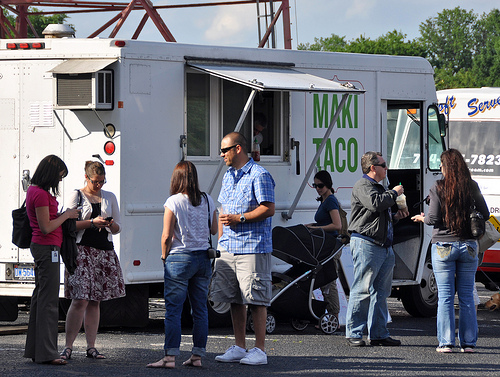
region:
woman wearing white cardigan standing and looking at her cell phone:
[53, 159, 125, 362]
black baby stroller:
[248, 220, 350, 336]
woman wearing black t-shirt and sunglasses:
[305, 170, 344, 333]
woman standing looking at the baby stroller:
[265, 164, 345, 336]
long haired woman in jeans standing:
[410, 147, 495, 353]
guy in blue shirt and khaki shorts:
[209, 127, 274, 365]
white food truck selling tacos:
[0, 32, 462, 325]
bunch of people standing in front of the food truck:
[7, 129, 498, 366]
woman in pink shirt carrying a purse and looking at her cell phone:
[10, 152, 80, 368]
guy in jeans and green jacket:
[343, 145, 407, 350]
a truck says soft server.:
[427, 82, 499, 131]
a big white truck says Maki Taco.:
[306, 82, 367, 174]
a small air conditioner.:
[50, 64, 117, 113]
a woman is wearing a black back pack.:
[9, 195, 35, 250]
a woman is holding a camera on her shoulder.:
[199, 187, 223, 261]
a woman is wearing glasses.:
[309, 180, 329, 192]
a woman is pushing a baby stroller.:
[262, 212, 339, 334]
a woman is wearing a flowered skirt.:
[56, 242, 126, 302]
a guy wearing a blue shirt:
[202, 127, 284, 368]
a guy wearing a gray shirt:
[340, 139, 405, 333]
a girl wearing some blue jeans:
[391, 158, 489, 341]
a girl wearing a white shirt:
[147, 169, 228, 329]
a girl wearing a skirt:
[71, 149, 141, 348]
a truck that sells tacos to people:
[53, 37, 443, 167]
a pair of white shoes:
[208, 339, 263, 374]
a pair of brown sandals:
[140, 348, 210, 375]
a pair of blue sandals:
[58, 337, 104, 367]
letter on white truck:
[309, 93, 329, 128]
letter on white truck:
[327, 93, 339, 128]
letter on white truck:
[343, 90, 357, 131]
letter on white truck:
[352, 93, 359, 131]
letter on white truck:
[311, 135, 323, 174]